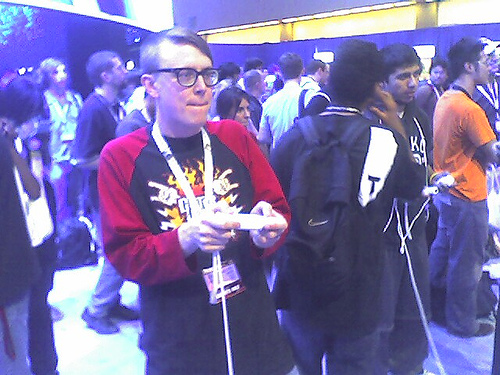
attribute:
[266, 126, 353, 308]
backpack — black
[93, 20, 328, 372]
man — young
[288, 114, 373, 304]
backpack — large, black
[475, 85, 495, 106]
landyard — white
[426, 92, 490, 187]
shirt — yellow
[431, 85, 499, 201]
t-shirt — orange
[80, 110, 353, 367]
shirt — white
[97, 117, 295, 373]
t-shirt — printed, red, black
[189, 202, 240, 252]
hand — white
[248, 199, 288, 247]
hand — white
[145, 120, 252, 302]
lanyard — white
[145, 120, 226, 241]
lanyard — white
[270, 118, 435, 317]
backpack — black 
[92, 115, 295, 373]
shirt — red, black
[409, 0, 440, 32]
light — wall light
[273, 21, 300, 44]
light — wall light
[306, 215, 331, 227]
logo — Nike, swoosh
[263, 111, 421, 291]
shirt — black, white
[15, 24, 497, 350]
crowd — group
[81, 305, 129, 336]
shoe — black, man's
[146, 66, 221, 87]
glasses — black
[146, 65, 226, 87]
eye glasses — pair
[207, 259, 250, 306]
tag — white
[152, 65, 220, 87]
frame — black